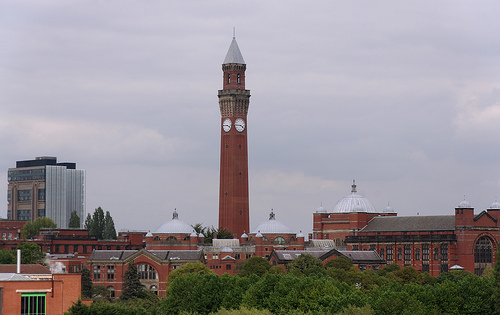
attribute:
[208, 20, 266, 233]
tower — Tall red 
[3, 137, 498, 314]
town — middle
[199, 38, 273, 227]
clock tower — Clock  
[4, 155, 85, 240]
building — large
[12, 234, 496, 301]
buildings — Red bricj,  without clock faces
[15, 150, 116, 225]
building — side 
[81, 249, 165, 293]
building — side 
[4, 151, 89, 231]
building — side 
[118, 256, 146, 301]
tree — green leafy, Group 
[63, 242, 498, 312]
trees — Group 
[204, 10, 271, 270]
tower — long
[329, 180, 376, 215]
dome — white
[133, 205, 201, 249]
roof — white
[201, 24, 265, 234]
tower — face , large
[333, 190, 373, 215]
dome roof — White domed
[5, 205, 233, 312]
trees — green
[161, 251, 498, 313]
shrubs — green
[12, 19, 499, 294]
building — red bricked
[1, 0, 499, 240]
grey sky — gray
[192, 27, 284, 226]
tallest building — tallest , Lookout 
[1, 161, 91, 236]
building — yellow bricked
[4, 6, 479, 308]
photo — forefront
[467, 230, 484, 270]
building — side 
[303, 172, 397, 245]
building — dome shaped, Top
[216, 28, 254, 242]
clock tower — long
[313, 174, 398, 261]
building — red bricked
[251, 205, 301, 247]
building — red bricked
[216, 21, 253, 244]
building — red bricked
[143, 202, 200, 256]
building — red bricked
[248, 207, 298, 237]
dome — white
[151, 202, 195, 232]
dome — white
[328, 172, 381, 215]
roof — white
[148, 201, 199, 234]
roof — white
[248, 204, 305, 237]
roof — white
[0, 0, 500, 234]
sky — foggy, white, gray, very cloudy